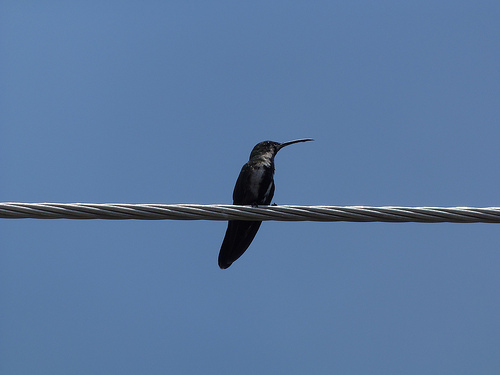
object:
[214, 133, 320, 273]
bird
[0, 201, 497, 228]
wire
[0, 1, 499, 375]
sky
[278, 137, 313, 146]
beak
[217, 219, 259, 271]
tail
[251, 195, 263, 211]
foot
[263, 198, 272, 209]
foot